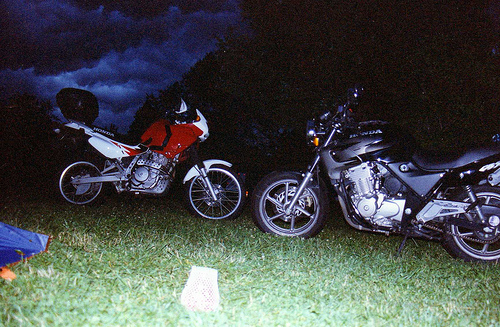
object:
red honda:
[55, 87, 247, 222]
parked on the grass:
[0, 158, 499, 327]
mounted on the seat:
[55, 87, 101, 126]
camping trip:
[0, 222, 51, 267]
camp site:
[1, 1, 498, 327]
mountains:
[0, 0, 500, 170]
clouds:
[1, 0, 251, 140]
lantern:
[179, 265, 221, 315]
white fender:
[182, 158, 233, 185]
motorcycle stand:
[396, 230, 410, 256]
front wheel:
[185, 166, 246, 221]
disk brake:
[272, 190, 306, 222]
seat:
[91, 123, 140, 145]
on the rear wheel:
[57, 160, 104, 205]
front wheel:
[250, 170, 332, 240]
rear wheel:
[441, 184, 500, 264]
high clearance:
[51, 118, 104, 206]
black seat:
[408, 143, 499, 175]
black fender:
[320, 174, 332, 208]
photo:
[0, 0, 499, 327]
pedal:
[391, 219, 402, 228]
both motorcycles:
[249, 83, 500, 264]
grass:
[0, 198, 500, 326]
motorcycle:
[53, 85, 249, 222]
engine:
[115, 150, 176, 195]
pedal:
[112, 181, 126, 194]